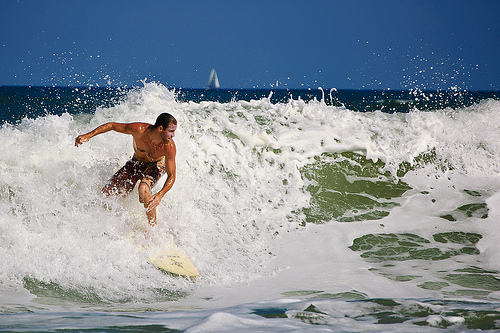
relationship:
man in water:
[72, 112, 198, 253] [1, 86, 499, 331]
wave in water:
[0, 83, 496, 243] [1, 86, 499, 331]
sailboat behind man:
[204, 66, 227, 90] [72, 112, 198, 253]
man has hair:
[72, 112, 198, 253] [156, 113, 178, 127]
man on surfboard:
[72, 112, 198, 253] [78, 185, 231, 284]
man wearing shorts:
[72, 112, 198, 253] [105, 150, 161, 205]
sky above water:
[1, 0, 499, 89] [1, 86, 499, 331]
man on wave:
[72, 112, 198, 253] [0, 83, 496, 243]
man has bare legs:
[72, 112, 198, 253] [107, 182, 163, 221]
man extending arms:
[72, 112, 198, 253] [61, 122, 188, 212]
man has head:
[72, 112, 198, 253] [152, 111, 180, 143]